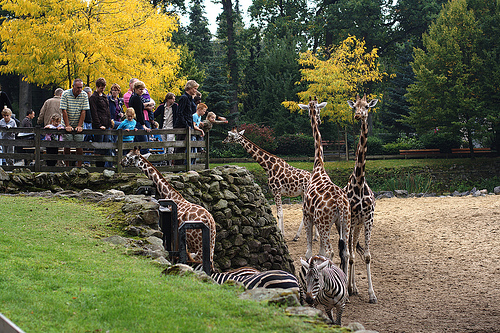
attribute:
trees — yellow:
[1, 1, 191, 108]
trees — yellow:
[281, 33, 397, 128]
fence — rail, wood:
[1, 126, 211, 172]